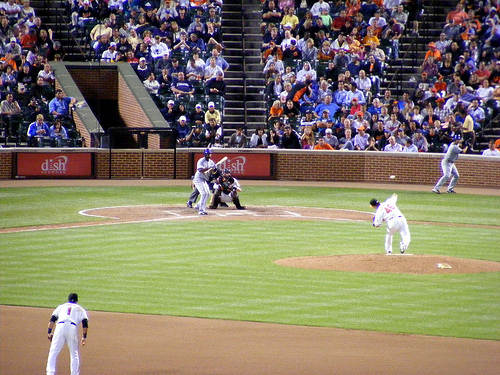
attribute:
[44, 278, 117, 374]
player — number 1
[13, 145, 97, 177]
sign — red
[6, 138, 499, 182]
wall — short, brick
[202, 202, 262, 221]
home plate — white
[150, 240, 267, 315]
grass — green